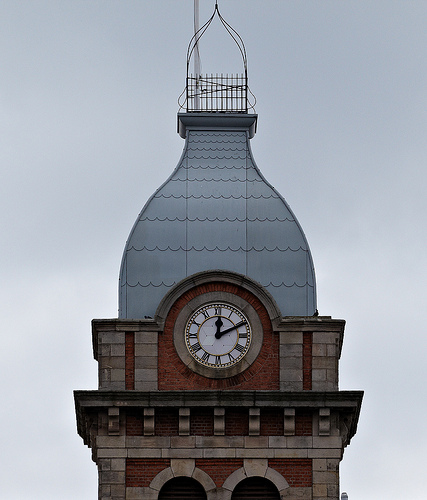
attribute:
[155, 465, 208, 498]
arc — black 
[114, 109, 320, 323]
roof — blue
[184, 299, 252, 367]
clock — black , white 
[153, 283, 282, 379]
clock — tall 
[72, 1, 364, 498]
building — stone , brick 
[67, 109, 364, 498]
tower — blue, clock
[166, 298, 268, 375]
clock — gray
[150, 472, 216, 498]
space — dark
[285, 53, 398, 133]
sky — gray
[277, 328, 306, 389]
stone line — white 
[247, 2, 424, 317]
sky — gray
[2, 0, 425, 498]
sky — cloudy , grey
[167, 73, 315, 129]
metal gate — black 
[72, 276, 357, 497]
red tower — pictured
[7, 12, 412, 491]
building — red